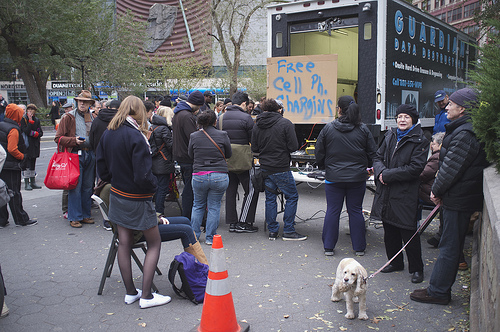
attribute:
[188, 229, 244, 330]
safety cone — orange and white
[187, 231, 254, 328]
cone — Orange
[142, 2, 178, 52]
tarp — Large, gray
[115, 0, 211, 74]
structure — brown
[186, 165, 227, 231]
jeans —  blue 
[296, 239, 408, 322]
dog — small , white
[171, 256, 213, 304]
backpack — Purple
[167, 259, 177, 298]
straps — black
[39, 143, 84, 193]
bag — red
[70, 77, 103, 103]
hat — brown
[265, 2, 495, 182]
truck — large, black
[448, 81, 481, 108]
hat — blue, ski 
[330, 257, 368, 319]
dog — white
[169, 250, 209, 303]
backpack — purple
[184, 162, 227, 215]
jeans — blue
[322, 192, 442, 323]
dog — Small, beige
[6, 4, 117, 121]
tree — background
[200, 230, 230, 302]
strips — gray